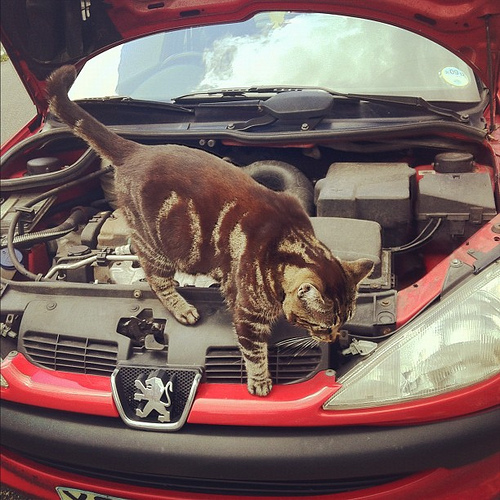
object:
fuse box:
[414, 171, 498, 254]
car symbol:
[133, 375, 174, 423]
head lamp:
[321, 256, 499, 411]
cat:
[40, 64, 374, 397]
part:
[305, 215, 383, 277]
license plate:
[57, 486, 125, 500]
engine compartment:
[0, 126, 500, 295]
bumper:
[0, 399, 499, 482]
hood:
[0, 0, 499, 117]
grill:
[21, 318, 323, 386]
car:
[0, 1, 499, 499]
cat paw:
[245, 380, 274, 397]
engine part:
[241, 158, 314, 218]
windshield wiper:
[168, 87, 302, 104]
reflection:
[191, 10, 483, 102]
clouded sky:
[66, 10, 481, 105]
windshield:
[68, 10, 483, 103]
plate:
[31, 465, 126, 497]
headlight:
[313, 253, 499, 414]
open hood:
[0, 0, 499, 340]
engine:
[0, 151, 499, 287]